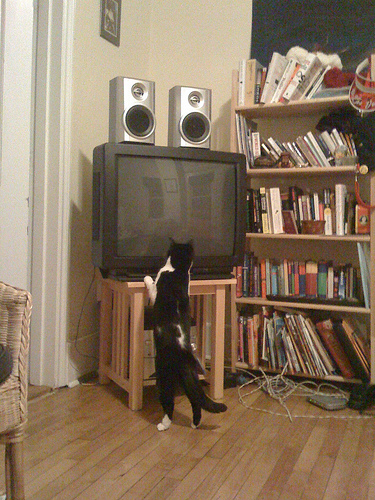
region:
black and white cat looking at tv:
[142, 238, 225, 434]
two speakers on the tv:
[107, 76, 212, 151]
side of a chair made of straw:
[1, 278, 33, 498]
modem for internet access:
[305, 392, 345, 410]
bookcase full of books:
[230, 51, 374, 385]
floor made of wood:
[27, 375, 374, 498]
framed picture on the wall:
[98, 0, 119, 49]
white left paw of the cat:
[156, 412, 171, 429]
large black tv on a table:
[89, 142, 245, 279]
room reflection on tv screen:
[114, 153, 236, 258]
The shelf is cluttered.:
[230, 56, 374, 111]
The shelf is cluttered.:
[227, 101, 370, 176]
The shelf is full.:
[241, 168, 373, 239]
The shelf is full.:
[229, 234, 374, 311]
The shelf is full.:
[231, 294, 372, 386]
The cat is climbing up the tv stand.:
[81, 134, 255, 434]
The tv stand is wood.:
[86, 262, 239, 413]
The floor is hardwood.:
[2, 366, 372, 499]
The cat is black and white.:
[138, 231, 233, 443]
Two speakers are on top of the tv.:
[77, 63, 252, 283]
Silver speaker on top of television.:
[111, 97, 155, 133]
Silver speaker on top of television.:
[162, 90, 219, 158]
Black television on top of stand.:
[84, 145, 262, 253]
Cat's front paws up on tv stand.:
[136, 265, 215, 410]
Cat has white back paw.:
[152, 423, 172, 437]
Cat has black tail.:
[185, 374, 235, 422]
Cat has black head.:
[167, 234, 199, 272]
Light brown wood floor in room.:
[125, 430, 216, 499]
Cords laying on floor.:
[254, 368, 329, 428]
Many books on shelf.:
[243, 268, 353, 366]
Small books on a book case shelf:
[242, 250, 255, 298]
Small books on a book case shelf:
[236, 315, 255, 368]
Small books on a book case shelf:
[254, 313, 281, 374]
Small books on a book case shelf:
[279, 318, 318, 376]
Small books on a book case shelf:
[317, 320, 364, 391]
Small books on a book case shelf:
[330, 261, 369, 298]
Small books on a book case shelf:
[304, 253, 331, 298]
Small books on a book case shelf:
[281, 256, 305, 300]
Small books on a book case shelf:
[284, 182, 312, 247]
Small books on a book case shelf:
[311, 186, 335, 246]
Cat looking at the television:
[116, 217, 229, 451]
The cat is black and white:
[133, 225, 274, 452]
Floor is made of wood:
[161, 430, 212, 498]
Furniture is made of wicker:
[3, 294, 33, 376]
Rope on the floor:
[240, 363, 331, 422]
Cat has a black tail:
[172, 354, 258, 443]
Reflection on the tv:
[132, 162, 210, 226]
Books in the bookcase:
[242, 128, 361, 304]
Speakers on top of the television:
[103, 59, 243, 151]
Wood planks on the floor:
[82, 451, 166, 498]